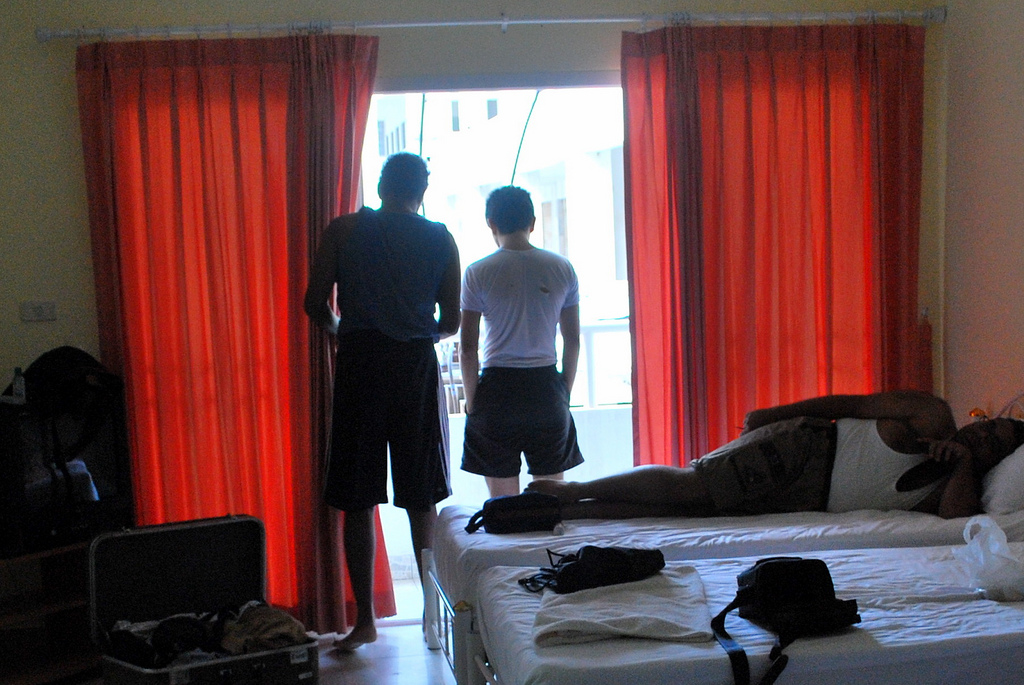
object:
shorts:
[460, 359, 586, 479]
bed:
[465, 542, 1024, 685]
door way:
[354, 86, 638, 584]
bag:
[709, 557, 860, 685]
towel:
[532, 565, 712, 648]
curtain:
[619, 23, 929, 469]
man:
[301, 153, 463, 651]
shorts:
[320, 338, 451, 510]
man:
[523, 390, 1024, 520]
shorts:
[688, 417, 835, 518]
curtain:
[76, 32, 401, 626]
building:
[0, 0, 1024, 685]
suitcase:
[80, 512, 319, 685]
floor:
[273, 623, 476, 685]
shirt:
[462, 248, 582, 370]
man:
[458, 185, 586, 499]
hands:
[465, 391, 482, 415]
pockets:
[463, 396, 480, 417]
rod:
[35, 4, 952, 46]